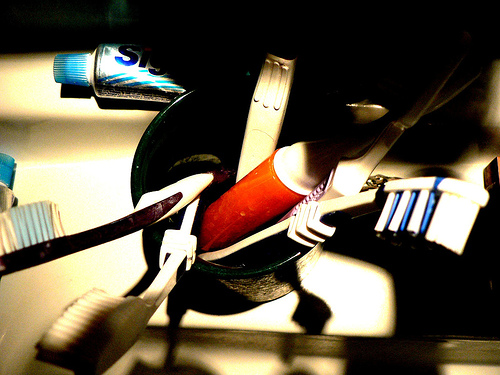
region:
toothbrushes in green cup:
[29, 19, 494, 355]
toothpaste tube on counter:
[46, 38, 192, 110]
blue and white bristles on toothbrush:
[364, 172, 464, 243]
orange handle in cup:
[184, 147, 326, 251]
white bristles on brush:
[37, 279, 146, 357]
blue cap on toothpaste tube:
[36, 38, 99, 103]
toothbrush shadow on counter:
[280, 279, 337, 344]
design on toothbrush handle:
[246, 57, 292, 115]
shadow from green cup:
[187, 295, 268, 317]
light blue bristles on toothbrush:
[8, 203, 65, 246]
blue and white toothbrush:
[374, 168, 486, 221]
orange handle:
[211, 160, 291, 224]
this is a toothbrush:
[36, 264, 183, 374]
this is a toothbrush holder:
[216, 247, 365, 329]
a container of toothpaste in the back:
[46, 26, 275, 173]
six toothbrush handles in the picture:
[120, 103, 492, 330]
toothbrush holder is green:
[214, 257, 439, 332]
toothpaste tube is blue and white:
[27, 61, 260, 131]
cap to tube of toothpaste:
[20, 49, 102, 86]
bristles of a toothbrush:
[372, 176, 474, 229]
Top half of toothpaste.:
[41, 38, 178, 103]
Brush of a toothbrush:
[364, 179, 499, 261]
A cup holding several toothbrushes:
[1, 34, 494, 372]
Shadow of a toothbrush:
[259, 251, 338, 339]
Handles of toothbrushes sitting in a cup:
[123, 55, 373, 294]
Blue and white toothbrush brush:
[3, 188, 77, 279]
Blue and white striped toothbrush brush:
[364, 158, 479, 258]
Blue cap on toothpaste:
[46, 48, 94, 88]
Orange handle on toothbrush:
[203, 153, 308, 257]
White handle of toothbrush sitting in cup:
[231, 37, 301, 199]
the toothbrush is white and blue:
[202, 172, 489, 287]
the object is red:
[197, 114, 344, 252]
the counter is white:
[34, 124, 121, 198]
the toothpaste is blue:
[40, 40, 239, 118]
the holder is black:
[115, 105, 235, 162]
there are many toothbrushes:
[1, 150, 493, 371]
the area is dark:
[235, 12, 494, 49]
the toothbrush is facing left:
[22, 252, 244, 367]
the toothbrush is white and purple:
[2, 159, 238, 286]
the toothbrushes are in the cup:
[15, 11, 490, 358]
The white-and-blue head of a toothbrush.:
[377, 169, 481, 258]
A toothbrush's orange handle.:
[205, 156, 292, 245]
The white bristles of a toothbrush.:
[33, 284, 108, 339]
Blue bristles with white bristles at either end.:
[0, 204, 82, 234]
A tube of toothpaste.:
[32, 36, 180, 102]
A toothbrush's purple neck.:
[62, 201, 193, 243]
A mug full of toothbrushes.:
[1, 75, 471, 368]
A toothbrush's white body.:
[237, 51, 291, 165]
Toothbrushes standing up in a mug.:
[85, 5, 465, 368]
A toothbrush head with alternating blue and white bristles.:
[355, 166, 485, 248]